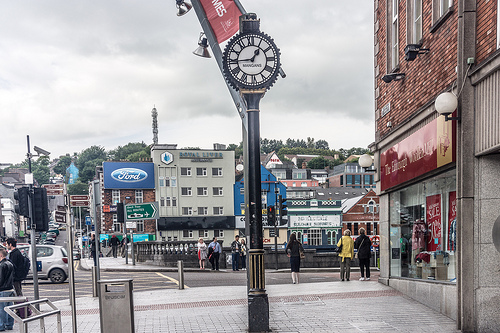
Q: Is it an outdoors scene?
A: Yes, it is outdoors.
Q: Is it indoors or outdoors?
A: It is outdoors.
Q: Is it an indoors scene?
A: No, it is outdoors.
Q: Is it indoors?
A: No, it is outdoors.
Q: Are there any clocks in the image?
A: Yes, there is a clock.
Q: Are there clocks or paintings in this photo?
A: Yes, there is a clock.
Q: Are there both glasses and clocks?
A: No, there is a clock but no glasses.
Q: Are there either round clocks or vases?
A: Yes, there is a round clock.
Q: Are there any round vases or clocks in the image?
A: Yes, there is a round clock.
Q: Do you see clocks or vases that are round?
A: Yes, the clock is round.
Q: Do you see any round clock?
A: Yes, there is a round clock.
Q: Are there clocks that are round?
A: Yes, there is a clock that is round.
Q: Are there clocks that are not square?
A: Yes, there is a round clock.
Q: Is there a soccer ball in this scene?
A: No, there are no soccer balls.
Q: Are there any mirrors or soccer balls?
A: No, there are no soccer balls or mirrors.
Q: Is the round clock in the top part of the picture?
A: Yes, the clock is in the top of the image.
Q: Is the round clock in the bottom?
A: No, the clock is in the top of the image.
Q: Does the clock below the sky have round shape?
A: Yes, the clock is round.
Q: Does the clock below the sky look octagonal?
A: No, the clock is round.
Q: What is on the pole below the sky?
A: The clock is on the pole.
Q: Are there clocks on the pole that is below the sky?
A: Yes, there is a clock on the pole.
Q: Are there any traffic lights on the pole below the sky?
A: No, there is a clock on the pole.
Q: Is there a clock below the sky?
A: Yes, there is a clock below the sky.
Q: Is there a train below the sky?
A: No, there is a clock below the sky.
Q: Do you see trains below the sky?
A: No, there is a clock below the sky.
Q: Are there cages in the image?
A: No, there are no cages.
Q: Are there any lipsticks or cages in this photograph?
A: No, there are no cages or lipsticks.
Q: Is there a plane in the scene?
A: No, there are no airplanes.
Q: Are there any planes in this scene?
A: No, there are no planes.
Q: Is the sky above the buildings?
A: Yes, the sky is above the buildings.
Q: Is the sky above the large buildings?
A: Yes, the sky is above the buildings.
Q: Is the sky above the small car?
A: Yes, the sky is above the car.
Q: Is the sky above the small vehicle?
A: Yes, the sky is above the car.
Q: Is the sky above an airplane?
A: No, the sky is above the car.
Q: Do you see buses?
A: No, there are no buses.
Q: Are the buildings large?
A: Yes, the buildings are large.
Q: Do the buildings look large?
A: Yes, the buildings are large.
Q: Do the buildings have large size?
A: Yes, the buildings are large.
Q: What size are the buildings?
A: The buildings are large.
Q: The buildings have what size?
A: The buildings are large.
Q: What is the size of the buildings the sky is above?
A: The buildings are large.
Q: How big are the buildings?
A: The buildings are large.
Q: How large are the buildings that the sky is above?
A: The buildings are large.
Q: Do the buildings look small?
A: No, the buildings are large.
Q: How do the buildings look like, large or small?
A: The buildings are large.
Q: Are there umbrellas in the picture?
A: No, there are no umbrellas.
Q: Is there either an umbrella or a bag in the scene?
A: No, there are no umbrellas or bags.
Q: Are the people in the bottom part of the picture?
A: Yes, the people are in the bottom of the image.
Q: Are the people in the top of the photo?
A: No, the people are in the bottom of the image.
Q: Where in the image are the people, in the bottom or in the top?
A: The people are in the bottom of the image.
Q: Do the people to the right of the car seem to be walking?
A: Yes, the people are walking.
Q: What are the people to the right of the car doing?
A: The people are walking.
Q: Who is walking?
A: The people are walking.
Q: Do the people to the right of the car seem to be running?
A: No, the people are walking.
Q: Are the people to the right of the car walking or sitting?
A: The people are walking.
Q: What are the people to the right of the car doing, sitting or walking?
A: The people are walking.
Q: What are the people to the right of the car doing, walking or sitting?
A: The people are walking.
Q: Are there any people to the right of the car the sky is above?
A: Yes, there are people to the right of the car.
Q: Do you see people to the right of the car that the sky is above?
A: Yes, there are people to the right of the car.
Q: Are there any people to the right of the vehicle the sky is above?
A: Yes, there are people to the right of the car.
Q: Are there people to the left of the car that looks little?
A: No, the people are to the right of the car.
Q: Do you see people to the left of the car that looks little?
A: No, the people are to the right of the car.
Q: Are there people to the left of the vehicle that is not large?
A: No, the people are to the right of the car.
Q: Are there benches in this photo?
A: No, there are no benches.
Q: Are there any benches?
A: No, there are no benches.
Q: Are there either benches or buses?
A: No, there are no benches or buses.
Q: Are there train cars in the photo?
A: No, there are no train cars.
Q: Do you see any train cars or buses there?
A: No, there are no train cars or buses.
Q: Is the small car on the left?
A: Yes, the car is on the left of the image.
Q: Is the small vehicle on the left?
A: Yes, the car is on the left of the image.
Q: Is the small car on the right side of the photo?
A: No, the car is on the left of the image.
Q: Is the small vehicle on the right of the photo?
A: No, the car is on the left of the image.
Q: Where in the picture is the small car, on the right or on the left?
A: The car is on the left of the image.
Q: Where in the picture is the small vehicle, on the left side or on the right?
A: The car is on the left of the image.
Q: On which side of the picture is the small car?
A: The car is on the left of the image.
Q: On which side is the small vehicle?
A: The car is on the left of the image.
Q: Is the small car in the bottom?
A: Yes, the car is in the bottom of the image.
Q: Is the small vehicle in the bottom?
A: Yes, the car is in the bottom of the image.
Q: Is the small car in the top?
A: No, the car is in the bottom of the image.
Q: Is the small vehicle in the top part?
A: No, the car is in the bottom of the image.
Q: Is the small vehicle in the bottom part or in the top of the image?
A: The car is in the bottom of the image.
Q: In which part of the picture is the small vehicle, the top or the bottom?
A: The car is in the bottom of the image.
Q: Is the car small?
A: Yes, the car is small.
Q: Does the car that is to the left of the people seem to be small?
A: Yes, the car is small.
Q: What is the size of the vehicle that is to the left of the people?
A: The car is small.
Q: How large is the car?
A: The car is small.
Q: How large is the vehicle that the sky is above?
A: The car is small.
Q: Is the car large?
A: No, the car is small.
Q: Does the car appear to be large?
A: No, the car is small.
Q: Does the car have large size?
A: No, the car is small.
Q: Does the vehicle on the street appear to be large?
A: No, the car is small.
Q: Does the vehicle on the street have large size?
A: No, the car is small.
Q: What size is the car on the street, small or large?
A: The car is small.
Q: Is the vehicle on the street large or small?
A: The car is small.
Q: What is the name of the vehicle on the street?
A: The vehicle is a car.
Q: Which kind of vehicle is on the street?
A: The vehicle is a car.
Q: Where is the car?
A: The car is on the street.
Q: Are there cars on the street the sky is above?
A: Yes, there is a car on the street.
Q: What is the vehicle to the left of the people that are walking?
A: The vehicle is a car.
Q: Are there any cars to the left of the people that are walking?
A: Yes, there is a car to the left of the people.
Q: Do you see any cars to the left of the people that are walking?
A: Yes, there is a car to the left of the people.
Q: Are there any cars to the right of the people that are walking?
A: No, the car is to the left of the people.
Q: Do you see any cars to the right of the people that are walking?
A: No, the car is to the left of the people.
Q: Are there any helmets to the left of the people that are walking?
A: No, there is a car to the left of the people.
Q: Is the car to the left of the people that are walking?
A: Yes, the car is to the left of the people.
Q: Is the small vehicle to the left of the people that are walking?
A: Yes, the car is to the left of the people.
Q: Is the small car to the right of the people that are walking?
A: No, the car is to the left of the people.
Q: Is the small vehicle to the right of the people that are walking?
A: No, the car is to the left of the people.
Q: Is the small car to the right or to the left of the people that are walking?
A: The car is to the left of the people.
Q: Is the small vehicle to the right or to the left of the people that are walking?
A: The car is to the left of the people.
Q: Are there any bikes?
A: No, there are no bikes.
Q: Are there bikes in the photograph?
A: No, there are no bikes.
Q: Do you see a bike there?
A: No, there are no bikes.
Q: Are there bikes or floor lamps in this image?
A: No, there are no bikes or floor lamps.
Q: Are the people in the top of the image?
A: No, the people are in the bottom of the image.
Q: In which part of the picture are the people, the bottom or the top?
A: The people are in the bottom of the image.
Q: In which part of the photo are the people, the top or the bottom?
A: The people are in the bottom of the image.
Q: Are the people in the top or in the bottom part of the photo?
A: The people are in the bottom of the image.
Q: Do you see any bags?
A: No, there are no bags.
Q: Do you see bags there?
A: No, there are no bags.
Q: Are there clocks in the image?
A: Yes, there is a clock.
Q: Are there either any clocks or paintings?
A: Yes, there is a clock.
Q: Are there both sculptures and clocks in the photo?
A: No, there is a clock but no sculptures.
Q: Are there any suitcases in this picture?
A: No, there are no suitcases.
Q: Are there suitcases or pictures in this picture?
A: No, there are no suitcases or pictures.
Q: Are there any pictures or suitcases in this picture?
A: No, there are no suitcases or pictures.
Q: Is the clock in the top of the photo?
A: Yes, the clock is in the top of the image.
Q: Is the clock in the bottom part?
A: No, the clock is in the top of the image.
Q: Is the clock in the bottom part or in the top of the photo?
A: The clock is in the top of the image.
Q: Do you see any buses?
A: No, there are no buses.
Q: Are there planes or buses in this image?
A: No, there are no buses or planes.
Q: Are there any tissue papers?
A: No, there are no tissue papers.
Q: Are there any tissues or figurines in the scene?
A: No, there are no tissues or figurines.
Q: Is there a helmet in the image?
A: No, there are no helmets.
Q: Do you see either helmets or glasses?
A: No, there are no helmets or glasses.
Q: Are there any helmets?
A: No, there are no helmets.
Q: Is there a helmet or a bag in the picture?
A: No, there are no helmets or bags.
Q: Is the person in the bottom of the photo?
A: Yes, the person is in the bottom of the image.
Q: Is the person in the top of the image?
A: No, the person is in the bottom of the image.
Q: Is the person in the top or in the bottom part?
A: The person is in the bottom of the image.